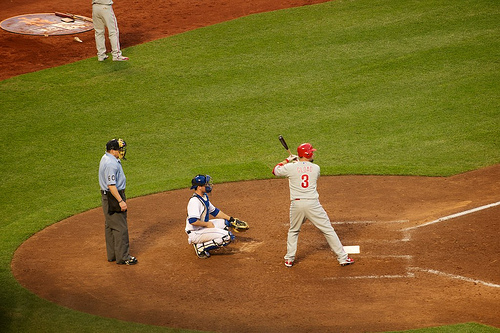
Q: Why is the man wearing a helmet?
A: Protection.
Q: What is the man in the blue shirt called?
A: Umpire.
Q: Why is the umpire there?
A: To call the pitch.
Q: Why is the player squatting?
A: Catch the pitch.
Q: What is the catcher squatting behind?
A: Home plate.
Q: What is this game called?
A: Baseball.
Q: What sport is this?
A: Baseball.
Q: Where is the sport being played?
A: Baseball field.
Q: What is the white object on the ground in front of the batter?
A: Baseball diamond.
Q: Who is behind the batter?
A: Catcher.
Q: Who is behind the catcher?
A: Umpire.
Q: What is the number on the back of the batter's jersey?
A: 3.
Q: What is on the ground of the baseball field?
A: Grass.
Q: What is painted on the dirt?
A: White lines.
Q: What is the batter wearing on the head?
A: Helmet.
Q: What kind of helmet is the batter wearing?
A: Red helmet.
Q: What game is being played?
A: Baseball.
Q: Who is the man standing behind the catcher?
A: Umpire.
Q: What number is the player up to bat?
A: 3.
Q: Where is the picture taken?
A: Baseball game.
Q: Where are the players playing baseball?
A: A field.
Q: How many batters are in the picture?
A: One.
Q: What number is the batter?
A: 3.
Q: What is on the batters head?
A: A helmet.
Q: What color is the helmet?
A: Red.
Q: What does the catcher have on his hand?
A: A mit.